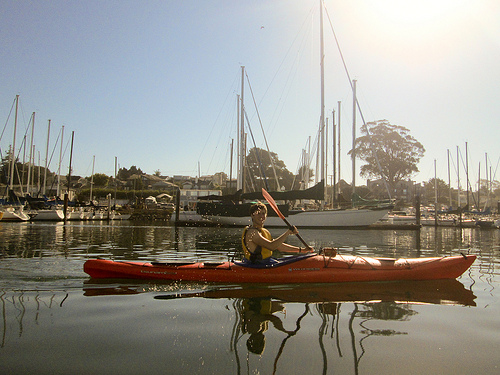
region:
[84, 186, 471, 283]
a man in the picture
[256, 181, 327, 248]
a man with a rowing stick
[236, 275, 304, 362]
the shadow of a man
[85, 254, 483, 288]
the boat is red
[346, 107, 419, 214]
the tree in the picutre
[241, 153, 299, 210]
the tree in the picutre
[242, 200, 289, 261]
the man is wearing yellow jacket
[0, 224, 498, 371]
calm waters in the lake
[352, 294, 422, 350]
a shadow of a tree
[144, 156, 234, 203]
buildings in the background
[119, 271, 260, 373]
the water is clear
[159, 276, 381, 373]
the water is clear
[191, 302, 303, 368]
the water is clear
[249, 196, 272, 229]
the head of a person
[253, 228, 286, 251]
the arm of a person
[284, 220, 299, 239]
the hand of a person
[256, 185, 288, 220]
a red oar read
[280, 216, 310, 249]
a black oar handle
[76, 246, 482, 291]
a red kayak on the water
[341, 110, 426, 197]
a leafy green tree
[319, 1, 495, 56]
white sun in the sky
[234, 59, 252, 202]
the mast of a boat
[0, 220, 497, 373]
the water of the harbor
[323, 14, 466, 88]
bright sunlight in the horizon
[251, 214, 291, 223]
wide grin on man's face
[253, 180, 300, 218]
red tip of oars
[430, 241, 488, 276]
red tip of boat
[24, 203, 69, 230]
water anchored at dock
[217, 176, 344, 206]
large black rolled up sail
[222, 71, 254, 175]
tall boat's mask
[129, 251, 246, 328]
small splash on water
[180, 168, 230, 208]
white house in the background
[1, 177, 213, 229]
lots of white boats anchored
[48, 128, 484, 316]
A person in a red kayak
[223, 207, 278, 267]
The person is wearing a lifevest.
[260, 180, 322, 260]
The person is holding a paddle.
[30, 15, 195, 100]
The sky is blue.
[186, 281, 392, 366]
A person is reflected in the water.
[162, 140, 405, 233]
A white boat in the background.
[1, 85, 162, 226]
Boats parked in the distance.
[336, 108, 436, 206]
A tree in the distance.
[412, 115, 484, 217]
Poles on boats.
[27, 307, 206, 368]
The water is brownish.